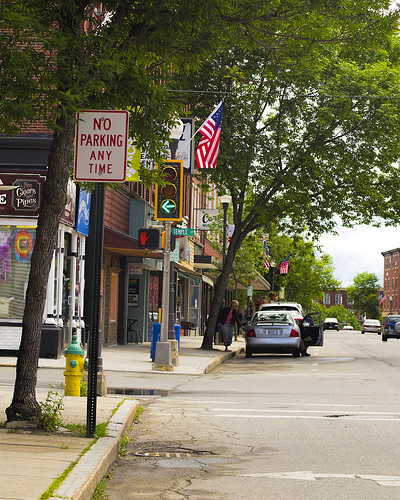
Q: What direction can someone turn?
A: Left.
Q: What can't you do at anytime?
A: Park.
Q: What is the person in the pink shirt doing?
A: Reaching for car door.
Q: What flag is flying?
A: American.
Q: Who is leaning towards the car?
A: A woman.